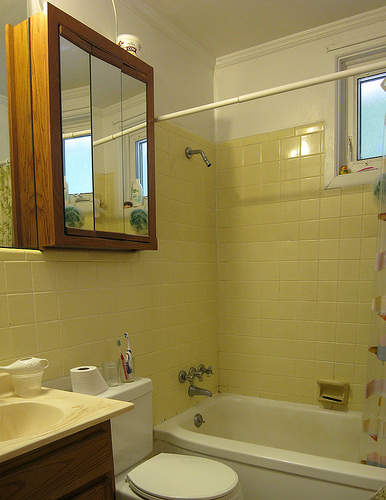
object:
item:
[320, 394, 341, 402]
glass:
[117, 358, 136, 382]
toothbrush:
[123, 331, 133, 376]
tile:
[300, 198, 321, 221]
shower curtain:
[357, 78, 386, 469]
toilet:
[0, 0, 385, 500]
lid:
[125, 452, 238, 500]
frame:
[4, 0, 158, 252]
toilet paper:
[69, 364, 109, 396]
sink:
[0, 402, 63, 440]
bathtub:
[152, 389, 385, 499]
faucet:
[178, 369, 194, 383]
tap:
[188, 384, 212, 397]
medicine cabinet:
[4, 0, 158, 253]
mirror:
[58, 35, 95, 231]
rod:
[153, 61, 385, 124]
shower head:
[184, 146, 212, 168]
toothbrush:
[115, 338, 129, 380]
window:
[356, 71, 385, 159]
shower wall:
[214, 6, 386, 412]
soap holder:
[316, 376, 350, 406]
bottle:
[130, 178, 143, 204]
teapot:
[0, 356, 49, 397]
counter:
[0, 385, 134, 463]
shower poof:
[129, 208, 148, 234]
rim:
[322, 25, 385, 191]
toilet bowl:
[94, 372, 245, 499]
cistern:
[95, 375, 156, 476]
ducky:
[338, 164, 348, 173]